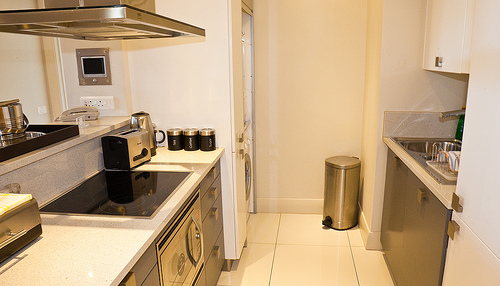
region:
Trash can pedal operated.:
[312, 150, 365, 241]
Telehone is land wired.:
[52, 100, 99, 122]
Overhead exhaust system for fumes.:
[1, 2, 216, 52]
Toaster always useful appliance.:
[100, 130, 157, 171]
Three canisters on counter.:
[165, 125, 218, 157]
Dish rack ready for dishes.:
[421, 139, 471, 179]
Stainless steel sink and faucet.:
[402, 103, 461, 155]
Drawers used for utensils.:
[200, 183, 235, 262]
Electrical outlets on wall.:
[77, 90, 124, 110]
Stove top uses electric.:
[44, 170, 181, 217]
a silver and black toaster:
[102, 127, 158, 168]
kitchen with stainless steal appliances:
[6, 26, 491, 278]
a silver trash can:
[317, 149, 365, 231]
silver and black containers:
[166, 124, 218, 156]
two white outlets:
[78, 95, 118, 111]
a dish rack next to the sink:
[423, 137, 468, 191]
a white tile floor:
[243, 204, 367, 282]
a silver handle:
[1, 110, 45, 141]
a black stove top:
[48, 157, 201, 227]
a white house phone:
[61, 104, 107, 122]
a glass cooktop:
[36, 141, 194, 254]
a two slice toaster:
[91, 108, 159, 188]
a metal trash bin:
[309, 141, 373, 251]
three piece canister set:
[161, 121, 223, 157]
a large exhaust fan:
[0, 1, 225, 66]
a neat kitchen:
[0, 3, 495, 270]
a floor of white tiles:
[241, 213, 391, 282]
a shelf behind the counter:
[1, 103, 133, 185]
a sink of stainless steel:
[389, 106, 465, 193]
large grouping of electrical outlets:
[72, 92, 129, 118]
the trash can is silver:
[313, 157, 367, 213]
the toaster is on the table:
[106, 123, 152, 166]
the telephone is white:
[60, 100, 103, 123]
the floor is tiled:
[273, 220, 331, 265]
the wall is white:
[152, 67, 211, 98]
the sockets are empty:
[87, 97, 114, 109]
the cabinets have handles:
[208, 169, 230, 262]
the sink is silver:
[403, 129, 457, 153]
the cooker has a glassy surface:
[95, 175, 167, 215]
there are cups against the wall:
[161, 132, 216, 151]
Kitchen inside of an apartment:
[2, 0, 493, 281]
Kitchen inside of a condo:
[7, 5, 494, 278]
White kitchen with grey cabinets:
[366, 145, 458, 276]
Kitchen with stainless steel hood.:
[5, 0, 190, 52]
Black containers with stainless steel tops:
[160, 107, 222, 162]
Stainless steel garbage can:
[316, 147, 365, 235]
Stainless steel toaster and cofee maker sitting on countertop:
[101, 110, 159, 169]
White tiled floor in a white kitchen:
[252, 208, 384, 284]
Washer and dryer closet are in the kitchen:
[235, 0, 271, 250]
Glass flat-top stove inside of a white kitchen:
[29, 157, 200, 234]